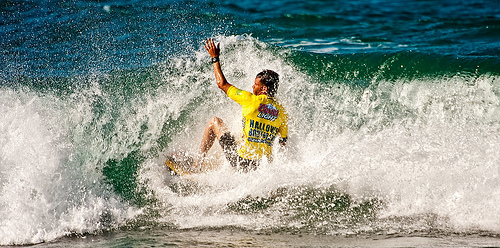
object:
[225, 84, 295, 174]
shirt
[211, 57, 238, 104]
arm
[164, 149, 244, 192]
surfboard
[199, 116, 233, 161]
leg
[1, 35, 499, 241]
water waves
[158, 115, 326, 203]
wakeboard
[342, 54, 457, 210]
water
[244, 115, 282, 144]
words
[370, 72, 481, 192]
foam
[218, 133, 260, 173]
black short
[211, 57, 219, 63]
watch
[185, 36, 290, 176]
man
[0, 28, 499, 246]
wave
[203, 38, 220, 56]
hand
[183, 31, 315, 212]
person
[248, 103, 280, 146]
writing